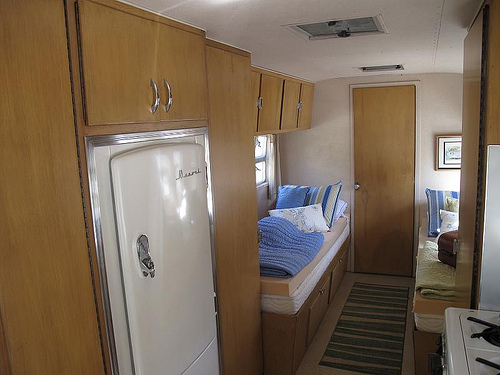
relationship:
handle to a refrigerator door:
[135, 229, 159, 273] [118, 142, 220, 371]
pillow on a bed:
[264, 201, 334, 244] [262, 185, 341, 305]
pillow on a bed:
[271, 182, 309, 221] [262, 212, 358, 304]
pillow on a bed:
[294, 180, 338, 220] [254, 181, 355, 318]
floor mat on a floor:
[318, 280, 411, 371] [331, 265, 420, 367]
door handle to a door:
[354, 182, 361, 190] [345, 78, 425, 283]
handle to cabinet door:
[141, 74, 165, 122] [78, 2, 162, 124]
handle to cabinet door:
[159, 74, 173, 108] [156, 22, 207, 124]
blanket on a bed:
[262, 210, 317, 278] [248, 190, 351, 310]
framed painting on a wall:
[433, 133, 465, 171] [423, 77, 483, 223]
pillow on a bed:
[276, 184, 311, 209] [264, 186, 348, 316]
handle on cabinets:
[150, 78, 161, 114] [68, 6, 212, 131]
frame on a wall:
[433, 130, 466, 176] [423, 81, 466, 199]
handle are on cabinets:
[150, 78, 161, 114] [68, 6, 221, 131]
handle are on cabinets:
[164, 78, 173, 113] [68, 6, 221, 131]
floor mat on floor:
[318, 280, 411, 371] [297, 267, 409, 373]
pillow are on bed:
[276, 184, 311, 209] [254, 181, 355, 318]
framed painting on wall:
[429, 128, 465, 173] [420, 80, 463, 189]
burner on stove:
[464, 310, 497, 347] [434, 301, 495, 372]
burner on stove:
[475, 355, 497, 371] [434, 301, 495, 372]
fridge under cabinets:
[86, 119, 233, 372] [68, 6, 221, 131]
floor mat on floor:
[318, 280, 411, 371] [295, 264, 417, 372]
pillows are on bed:
[422, 180, 456, 242] [412, 187, 462, 332]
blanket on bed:
[413, 232, 457, 303] [408, 199, 461, 333]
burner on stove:
[464, 310, 497, 347] [436, 299, 499, 372]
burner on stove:
[476, 353, 497, 371] [436, 299, 499, 372]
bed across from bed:
[257, 176, 351, 320] [408, 185, 461, 334]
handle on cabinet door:
[150, 78, 161, 114] [78, 2, 162, 124]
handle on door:
[164, 78, 173, 113] [160, 17, 215, 128]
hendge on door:
[252, 91, 268, 113] [249, 65, 285, 136]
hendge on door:
[292, 94, 307, 118] [284, 79, 313, 127]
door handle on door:
[354, 182, 361, 190] [345, 78, 425, 283]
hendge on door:
[316, 281, 328, 300] [306, 275, 339, 343]